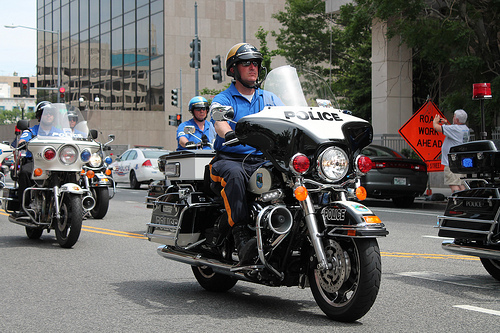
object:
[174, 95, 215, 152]
policeman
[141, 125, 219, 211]
motorcycle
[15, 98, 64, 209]
policeman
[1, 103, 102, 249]
motorcycle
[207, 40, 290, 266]
policeman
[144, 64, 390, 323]
motorcycle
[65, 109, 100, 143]
policeman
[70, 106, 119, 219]
motorcycle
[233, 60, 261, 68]
sunglasses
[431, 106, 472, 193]
man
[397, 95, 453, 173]
sign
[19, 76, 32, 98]
light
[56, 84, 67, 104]
light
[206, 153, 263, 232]
pants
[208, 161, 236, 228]
stripe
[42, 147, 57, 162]
light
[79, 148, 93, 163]
light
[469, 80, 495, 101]
light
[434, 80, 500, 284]
motorcycle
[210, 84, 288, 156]
shirt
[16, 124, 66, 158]
shirt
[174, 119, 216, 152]
shirt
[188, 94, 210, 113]
helmet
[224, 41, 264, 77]
helmet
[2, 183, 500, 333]
road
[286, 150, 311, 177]
light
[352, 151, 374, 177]
light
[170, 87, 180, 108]
light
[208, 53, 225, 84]
light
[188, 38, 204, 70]
light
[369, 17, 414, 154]
pillar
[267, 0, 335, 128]
trees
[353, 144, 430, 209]
car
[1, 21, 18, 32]
light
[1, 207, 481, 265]
line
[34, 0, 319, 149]
building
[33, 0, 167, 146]
wall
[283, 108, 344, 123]
police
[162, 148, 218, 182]
bin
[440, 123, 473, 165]
shirt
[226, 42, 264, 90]
head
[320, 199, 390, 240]
fender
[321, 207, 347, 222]
word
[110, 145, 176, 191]
car